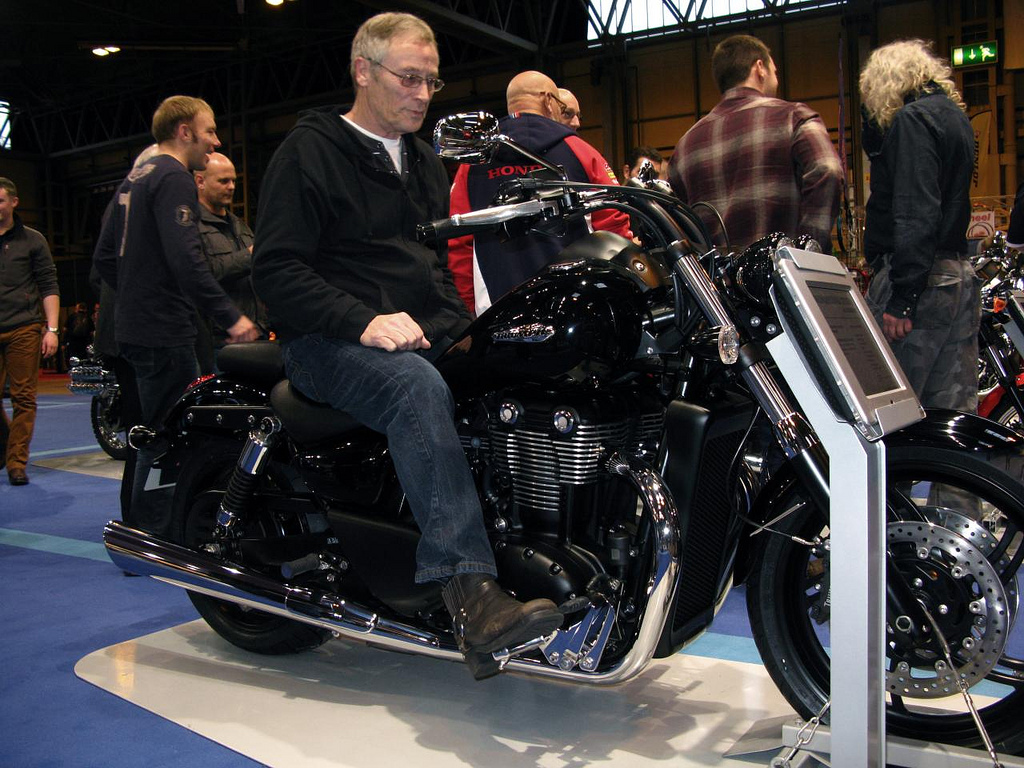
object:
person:
[623, 146, 662, 187]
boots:
[441, 575, 563, 681]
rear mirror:
[435, 112, 501, 165]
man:
[858, 41, 974, 405]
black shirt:
[862, 84, 972, 259]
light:
[105, 46, 120, 52]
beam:
[91, 49, 107, 57]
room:
[8, 1, 1015, 755]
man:
[254, 12, 557, 683]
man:
[681, 36, 837, 252]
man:
[195, 153, 256, 334]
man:
[0, 180, 54, 488]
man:
[453, 71, 625, 314]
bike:
[69, 111, 1020, 749]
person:
[94, 96, 250, 576]